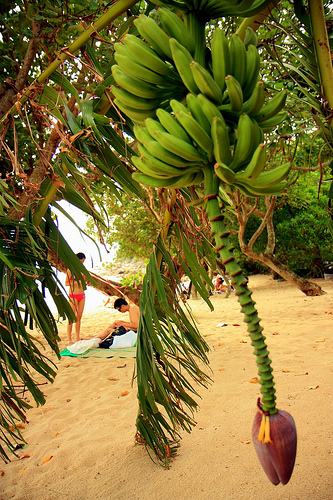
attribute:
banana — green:
[127, 110, 202, 167]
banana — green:
[235, 160, 292, 189]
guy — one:
[81, 297, 139, 339]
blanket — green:
[57, 340, 140, 362]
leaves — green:
[149, 266, 314, 488]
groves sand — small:
[54, 370, 128, 448]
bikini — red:
[62, 270, 93, 302]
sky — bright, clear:
[124, 131, 135, 143]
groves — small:
[250, 376, 259, 384]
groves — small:
[272, 330, 280, 335]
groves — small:
[40, 453, 53, 464]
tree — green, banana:
[99, 12, 320, 278]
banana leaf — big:
[131, 187, 215, 473]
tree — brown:
[84, 145, 326, 296]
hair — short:
[112, 287, 124, 306]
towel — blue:
[65, 337, 102, 355]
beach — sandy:
[54, 397, 127, 480]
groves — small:
[219, 354, 240, 477]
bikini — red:
[68, 294, 85, 303]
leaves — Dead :
[307, 384, 320, 392]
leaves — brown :
[35, 78, 144, 172]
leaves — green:
[59, 89, 119, 170]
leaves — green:
[137, 217, 207, 426]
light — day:
[56, 204, 119, 261]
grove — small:
[64, 396, 75, 407]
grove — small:
[111, 359, 128, 369]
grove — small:
[60, 363, 71, 370]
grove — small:
[114, 386, 130, 401]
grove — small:
[211, 333, 228, 348]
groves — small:
[282, 367, 291, 374]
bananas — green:
[122, 99, 295, 217]